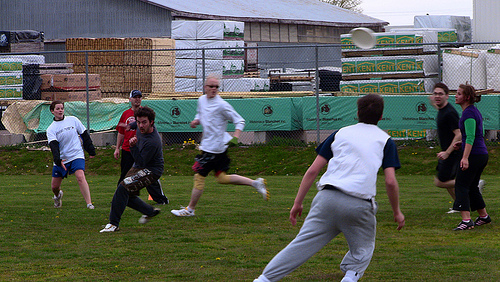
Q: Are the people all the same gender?
A: No, they are both male and female.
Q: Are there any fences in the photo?
A: Yes, there is a fence.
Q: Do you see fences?
A: Yes, there is a fence.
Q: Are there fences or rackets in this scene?
A: Yes, there is a fence.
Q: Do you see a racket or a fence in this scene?
A: Yes, there is a fence.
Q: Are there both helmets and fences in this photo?
A: No, there is a fence but no helmets.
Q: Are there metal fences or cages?
A: Yes, there is a metal fence.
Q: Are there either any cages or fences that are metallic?
A: Yes, the fence is metallic.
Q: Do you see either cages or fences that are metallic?
A: Yes, the fence is metallic.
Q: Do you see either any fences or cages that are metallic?
A: Yes, the fence is metallic.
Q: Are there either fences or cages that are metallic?
A: Yes, the fence is metallic.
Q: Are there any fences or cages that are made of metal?
A: Yes, the fence is made of metal.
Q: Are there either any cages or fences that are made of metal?
A: Yes, the fence is made of metal.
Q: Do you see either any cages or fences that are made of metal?
A: Yes, the fence is made of metal.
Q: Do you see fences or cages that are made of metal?
A: Yes, the fence is made of metal.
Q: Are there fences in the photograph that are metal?
A: Yes, there is a metal fence.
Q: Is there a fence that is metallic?
A: Yes, there is a fence that is metallic.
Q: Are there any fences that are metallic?
A: Yes, there is a fence that is metallic.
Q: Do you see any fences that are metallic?
A: Yes, there is a fence that is metallic.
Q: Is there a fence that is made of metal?
A: Yes, there is a fence that is made of metal.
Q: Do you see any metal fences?
A: Yes, there is a fence that is made of metal.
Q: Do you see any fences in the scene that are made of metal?
A: Yes, there is a fence that is made of metal.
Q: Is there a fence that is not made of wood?
A: Yes, there is a fence that is made of metal.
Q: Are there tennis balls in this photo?
A: No, there are no tennis balls.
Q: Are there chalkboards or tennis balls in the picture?
A: No, there are no tennis balls or chalkboards.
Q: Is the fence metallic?
A: Yes, the fence is metallic.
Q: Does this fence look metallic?
A: Yes, the fence is metallic.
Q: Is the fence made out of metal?
A: Yes, the fence is made of metal.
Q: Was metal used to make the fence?
A: Yes, the fence is made of metal.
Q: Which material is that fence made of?
A: The fence is made of metal.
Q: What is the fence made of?
A: The fence is made of metal.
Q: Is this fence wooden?
A: No, the fence is metallic.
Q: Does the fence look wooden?
A: No, the fence is metallic.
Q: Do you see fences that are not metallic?
A: No, there is a fence but it is metallic.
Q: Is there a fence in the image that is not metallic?
A: No, there is a fence but it is metallic.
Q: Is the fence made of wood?
A: No, the fence is made of metal.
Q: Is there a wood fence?
A: No, there is a fence but it is made of metal.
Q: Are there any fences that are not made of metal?
A: No, there is a fence but it is made of metal.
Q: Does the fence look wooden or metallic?
A: The fence is metallic.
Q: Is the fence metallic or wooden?
A: The fence is metallic.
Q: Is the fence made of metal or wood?
A: The fence is made of metal.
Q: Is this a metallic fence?
A: Yes, this is a metallic fence.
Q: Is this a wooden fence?
A: No, this is a metallic fence.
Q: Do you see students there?
A: No, there are no students.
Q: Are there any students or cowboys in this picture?
A: No, there are no students or cowboys.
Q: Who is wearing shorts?
A: The man is wearing shorts.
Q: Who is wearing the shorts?
A: The man is wearing shorts.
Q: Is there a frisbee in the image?
A: Yes, there is a frisbee.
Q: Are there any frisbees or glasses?
A: Yes, there is a frisbee.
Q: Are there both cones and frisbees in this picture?
A: No, there is a frisbee but no cones.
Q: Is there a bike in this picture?
A: No, there are no bikes.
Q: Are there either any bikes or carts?
A: No, there are no bikes or carts.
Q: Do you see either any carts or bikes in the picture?
A: No, there are no bikes or carts.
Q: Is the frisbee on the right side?
A: Yes, the frisbee is on the right of the image.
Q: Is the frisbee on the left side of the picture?
A: No, the frisbee is on the right of the image.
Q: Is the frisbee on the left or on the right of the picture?
A: The frisbee is on the right of the image.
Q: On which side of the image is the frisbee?
A: The frisbee is on the right of the image.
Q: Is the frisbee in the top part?
A: Yes, the frisbee is in the top of the image.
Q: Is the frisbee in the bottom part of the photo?
A: No, the frisbee is in the top of the image.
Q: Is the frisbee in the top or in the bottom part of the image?
A: The frisbee is in the top of the image.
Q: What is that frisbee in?
A: The frisbee is in the air.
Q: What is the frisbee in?
A: The frisbee is in the air.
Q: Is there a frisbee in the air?
A: Yes, there is a frisbee in the air.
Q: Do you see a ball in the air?
A: No, there is a frisbee in the air.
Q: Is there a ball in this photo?
A: No, there are no balls.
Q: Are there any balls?
A: No, there are no balls.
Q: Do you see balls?
A: No, there are no balls.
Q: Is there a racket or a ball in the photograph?
A: No, there are no balls or rackets.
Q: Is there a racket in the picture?
A: No, there are no rackets.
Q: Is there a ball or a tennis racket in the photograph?
A: No, there are no rackets or balls.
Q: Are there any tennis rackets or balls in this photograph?
A: No, there are no tennis rackets or balls.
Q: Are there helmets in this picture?
A: No, there are no helmets.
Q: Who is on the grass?
A: The man is on the grass.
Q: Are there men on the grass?
A: Yes, there is a man on the grass.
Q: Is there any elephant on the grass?
A: No, there is a man on the grass.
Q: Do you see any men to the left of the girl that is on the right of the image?
A: Yes, there is a man to the left of the girl.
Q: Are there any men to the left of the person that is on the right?
A: Yes, there is a man to the left of the girl.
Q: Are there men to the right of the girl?
A: No, the man is to the left of the girl.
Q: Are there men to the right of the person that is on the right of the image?
A: No, the man is to the left of the girl.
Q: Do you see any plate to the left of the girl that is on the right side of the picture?
A: No, there is a man to the left of the girl.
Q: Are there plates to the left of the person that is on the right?
A: No, there is a man to the left of the girl.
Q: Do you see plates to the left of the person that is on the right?
A: No, there is a man to the left of the girl.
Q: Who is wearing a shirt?
A: The man is wearing a shirt.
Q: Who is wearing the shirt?
A: The man is wearing a shirt.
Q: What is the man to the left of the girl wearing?
A: The man is wearing a shirt.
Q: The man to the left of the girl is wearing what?
A: The man is wearing a shirt.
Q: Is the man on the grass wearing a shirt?
A: Yes, the man is wearing a shirt.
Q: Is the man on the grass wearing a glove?
A: No, the man is wearing a shirt.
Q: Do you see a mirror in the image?
A: No, there are no mirrors.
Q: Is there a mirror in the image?
A: No, there are no mirrors.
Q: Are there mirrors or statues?
A: No, there are no mirrors or statues.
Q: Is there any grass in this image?
A: Yes, there is grass.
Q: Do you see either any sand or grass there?
A: Yes, there is grass.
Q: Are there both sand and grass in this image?
A: No, there is grass but no sand.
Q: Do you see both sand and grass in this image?
A: No, there is grass but no sand.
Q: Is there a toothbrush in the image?
A: No, there are no toothbrushes.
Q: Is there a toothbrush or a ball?
A: No, there are no toothbrushes or balls.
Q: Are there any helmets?
A: No, there are no helmets.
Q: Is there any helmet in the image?
A: No, there are no helmets.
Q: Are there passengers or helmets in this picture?
A: No, there are no helmets or passengers.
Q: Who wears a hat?
A: The man wears a hat.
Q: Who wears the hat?
A: The man wears a hat.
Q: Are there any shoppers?
A: No, there are no shoppers.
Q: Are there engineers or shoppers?
A: No, there are no shoppers or engineers.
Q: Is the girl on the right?
A: Yes, the girl is on the right of the image.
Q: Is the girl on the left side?
A: No, the girl is on the right of the image.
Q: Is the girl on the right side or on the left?
A: The girl is on the right of the image.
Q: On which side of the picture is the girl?
A: The girl is on the right of the image.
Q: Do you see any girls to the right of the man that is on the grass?
A: Yes, there is a girl to the right of the man.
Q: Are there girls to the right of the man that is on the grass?
A: Yes, there is a girl to the right of the man.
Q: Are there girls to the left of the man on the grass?
A: No, the girl is to the right of the man.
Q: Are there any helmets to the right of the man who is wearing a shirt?
A: No, there is a girl to the right of the man.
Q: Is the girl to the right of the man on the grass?
A: Yes, the girl is to the right of the man.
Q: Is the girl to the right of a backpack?
A: No, the girl is to the right of the man.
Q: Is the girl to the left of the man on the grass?
A: No, the girl is to the right of the man.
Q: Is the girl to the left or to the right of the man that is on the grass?
A: The girl is to the right of the man.